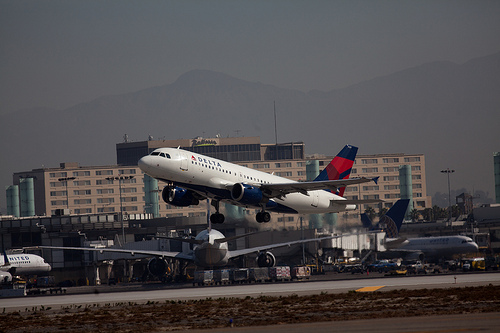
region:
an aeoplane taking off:
[133, 147, 390, 214]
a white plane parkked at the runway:
[1, 246, 56, 281]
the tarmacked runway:
[117, 275, 343, 292]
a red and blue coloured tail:
[338, 155, 358, 180]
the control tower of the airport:
[204, 136, 305, 158]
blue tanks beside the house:
[8, 178, 25, 215]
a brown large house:
[42, 178, 124, 206]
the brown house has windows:
[44, 186, 110, 198]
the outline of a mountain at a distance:
[117, 60, 258, 116]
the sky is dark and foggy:
[83, 28, 235, 54]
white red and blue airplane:
[134, 132, 364, 219]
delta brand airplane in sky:
[134, 128, 365, 233]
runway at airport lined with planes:
[10, 181, 494, 326]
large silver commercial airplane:
[39, 205, 379, 287]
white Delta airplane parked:
[376, 224, 483, 266]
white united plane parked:
[2, 247, 52, 289]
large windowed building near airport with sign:
[8, 125, 427, 243]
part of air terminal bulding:
[0, 203, 214, 283]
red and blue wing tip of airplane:
[310, 143, 363, 198]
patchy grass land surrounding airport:
[2, 285, 499, 326]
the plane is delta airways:
[139, 125, 366, 238]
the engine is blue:
[228, 181, 268, 215]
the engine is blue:
[163, 182, 202, 208]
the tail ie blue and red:
[320, 137, 367, 206]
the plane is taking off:
[141, 138, 377, 232]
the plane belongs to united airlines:
[2, 240, 63, 285]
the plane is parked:
[145, 216, 330, 267]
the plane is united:
[375, 200, 480, 271]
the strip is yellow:
[353, 279, 390, 299]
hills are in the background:
[186, 83, 464, 142]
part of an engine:
[232, 180, 253, 205]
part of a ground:
[358, 280, 386, 311]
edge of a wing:
[276, 235, 292, 252]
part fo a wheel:
[263, 207, 275, 227]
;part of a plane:
[186, 157, 218, 186]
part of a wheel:
[257, 202, 287, 235]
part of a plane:
[201, 159, 252, 236]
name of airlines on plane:
[182, 155, 239, 171]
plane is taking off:
[98, 115, 342, 249]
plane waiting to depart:
[43, 229, 324, 294]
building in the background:
[10, 155, 421, 211]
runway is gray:
[126, 282, 496, 295]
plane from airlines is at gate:
[3, 241, 58, 277]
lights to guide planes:
[436, 145, 454, 222]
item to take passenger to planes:
[93, 238, 183, 263]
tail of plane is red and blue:
[317, 145, 362, 197]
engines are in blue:
[156, 180, 272, 210]